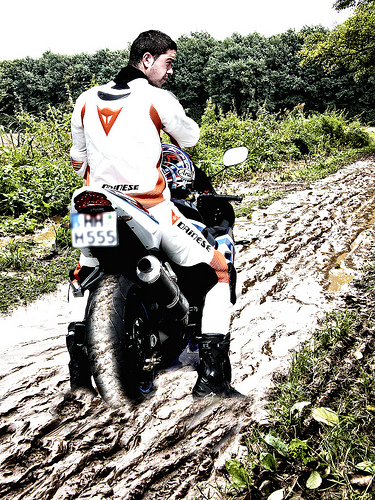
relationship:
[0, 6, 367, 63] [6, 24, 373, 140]
sky above trees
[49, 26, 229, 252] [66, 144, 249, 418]
man on bike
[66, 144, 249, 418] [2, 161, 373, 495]
bike on road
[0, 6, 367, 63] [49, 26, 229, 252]
sky above man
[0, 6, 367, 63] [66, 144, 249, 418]
sky above bike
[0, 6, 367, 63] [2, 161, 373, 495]
sky above road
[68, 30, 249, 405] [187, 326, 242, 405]
cyclist has shoe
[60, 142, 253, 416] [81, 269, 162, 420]
motorbike has wheel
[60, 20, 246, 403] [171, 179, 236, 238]
cyclist wears helmet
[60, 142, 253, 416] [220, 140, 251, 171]
motorbike has mirror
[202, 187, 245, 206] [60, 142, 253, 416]
handle bar has motorbike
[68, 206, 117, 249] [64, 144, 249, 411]
registration number on motorbike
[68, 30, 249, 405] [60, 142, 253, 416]
cyclist on motorbike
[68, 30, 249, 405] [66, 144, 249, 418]
cyclist rides bike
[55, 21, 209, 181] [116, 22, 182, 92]
man has head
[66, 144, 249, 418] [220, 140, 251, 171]
bike has mirror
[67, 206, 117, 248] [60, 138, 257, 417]
registration number on bike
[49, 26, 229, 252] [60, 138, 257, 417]
man riding bike